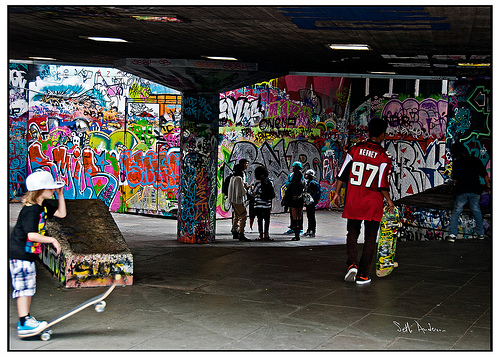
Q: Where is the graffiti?
A: On the wall, pillar, ramp.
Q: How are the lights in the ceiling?
A: Recessed.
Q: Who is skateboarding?
A: A kid.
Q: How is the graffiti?
A: Very colorful and artistic.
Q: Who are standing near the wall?
A: A group of kids.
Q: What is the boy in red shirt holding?
A: A skateboard.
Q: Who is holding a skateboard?
A: A boy in red shirt.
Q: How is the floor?
A: Grey and tiled.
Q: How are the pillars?
A: Concrete support pillars are full of graffiti.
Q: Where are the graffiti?
A: On the wall.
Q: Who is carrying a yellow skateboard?
A: A man.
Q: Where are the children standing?
A: At the walkway.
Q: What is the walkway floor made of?
A: Tiles and stones.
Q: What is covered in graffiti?
A: Concrete slab.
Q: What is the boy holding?
A: Skateboard.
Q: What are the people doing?
A: Standing.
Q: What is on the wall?
A: Colorful graffiti.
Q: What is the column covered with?
A: Graffiti.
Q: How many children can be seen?
A: 7.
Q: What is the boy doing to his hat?
A: Touching it.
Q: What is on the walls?
A: Graffiti.